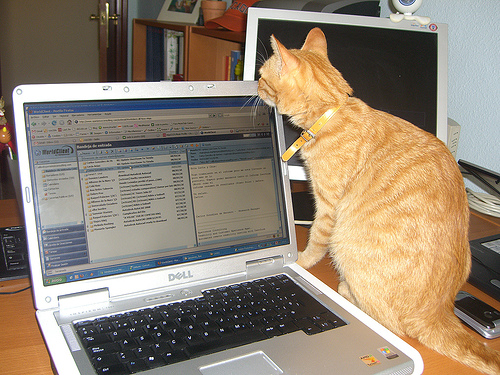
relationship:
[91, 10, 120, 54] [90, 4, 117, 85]
handle of door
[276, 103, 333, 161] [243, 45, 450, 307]
collar of cat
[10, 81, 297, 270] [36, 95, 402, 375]
lid of laptop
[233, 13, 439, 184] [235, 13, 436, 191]
monitor of computer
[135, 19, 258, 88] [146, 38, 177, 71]
shelves for books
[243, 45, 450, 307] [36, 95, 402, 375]
cat next to laptop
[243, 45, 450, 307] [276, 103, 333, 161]
cat wearing collar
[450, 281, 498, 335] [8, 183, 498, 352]
cellphone on table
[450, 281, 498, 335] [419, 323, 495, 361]
cellphone by tail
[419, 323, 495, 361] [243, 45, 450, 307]
tail of cat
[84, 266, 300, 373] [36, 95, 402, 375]
keyboard on laptop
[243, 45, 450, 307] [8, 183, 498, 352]
cat on table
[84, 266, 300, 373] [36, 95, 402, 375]
keyboard of laptop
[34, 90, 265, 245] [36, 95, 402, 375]
screen of laptop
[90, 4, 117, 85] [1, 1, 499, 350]
door of room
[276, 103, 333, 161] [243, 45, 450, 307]
collar on cat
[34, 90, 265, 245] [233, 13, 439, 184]
screen on monitor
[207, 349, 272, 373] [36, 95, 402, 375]
pad of laptop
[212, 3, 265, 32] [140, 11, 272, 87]
cap on shelf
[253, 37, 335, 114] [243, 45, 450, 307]
head of cat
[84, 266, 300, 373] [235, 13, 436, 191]
keyboard of computer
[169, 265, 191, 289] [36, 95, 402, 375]
writing on laptop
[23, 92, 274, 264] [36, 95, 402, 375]
monitor of laptop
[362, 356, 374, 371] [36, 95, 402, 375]
sticker on laptop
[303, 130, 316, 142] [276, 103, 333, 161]
buckle on collar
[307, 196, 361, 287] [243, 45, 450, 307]
leg of cat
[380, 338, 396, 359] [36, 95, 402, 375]
logo on laptop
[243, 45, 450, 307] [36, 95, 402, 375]
cat looking at laptop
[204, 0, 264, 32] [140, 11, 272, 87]
cap on shelf